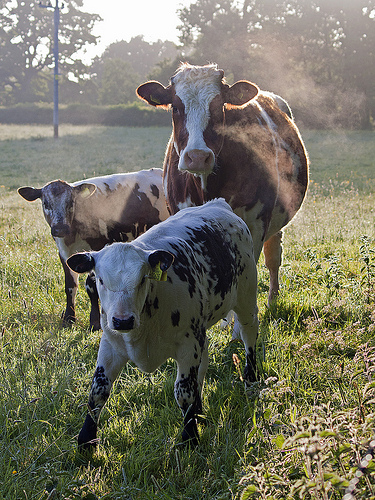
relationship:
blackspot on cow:
[168, 310, 183, 327] [64, 197, 259, 462]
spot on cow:
[169, 308, 181, 328] [64, 197, 259, 462]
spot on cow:
[169, 308, 181, 328] [17, 160, 171, 331]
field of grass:
[1, 125, 373, 498] [3, 122, 373, 498]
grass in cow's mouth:
[289, 251, 357, 341] [174, 161, 216, 177]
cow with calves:
[135, 62, 309, 301] [17, 166, 257, 460]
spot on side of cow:
[190, 217, 243, 303] [58, 194, 277, 453]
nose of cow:
[184, 151, 221, 174] [128, 58, 317, 219]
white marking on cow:
[174, 62, 214, 149] [138, 59, 300, 229]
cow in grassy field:
[64, 197, 259, 462] [1, 123, 373, 497]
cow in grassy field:
[135, 62, 309, 301] [1, 123, 373, 497]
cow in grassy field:
[16, 166, 169, 332] [1, 123, 373, 497]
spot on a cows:
[191, 351, 199, 361] [133, 55, 312, 325]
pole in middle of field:
[46, 1, 64, 140] [1, 125, 373, 498]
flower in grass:
[9, 468, 20, 475] [5, 332, 70, 497]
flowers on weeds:
[235, 351, 363, 488] [243, 351, 363, 483]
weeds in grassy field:
[243, 351, 363, 483] [1, 123, 373, 497]